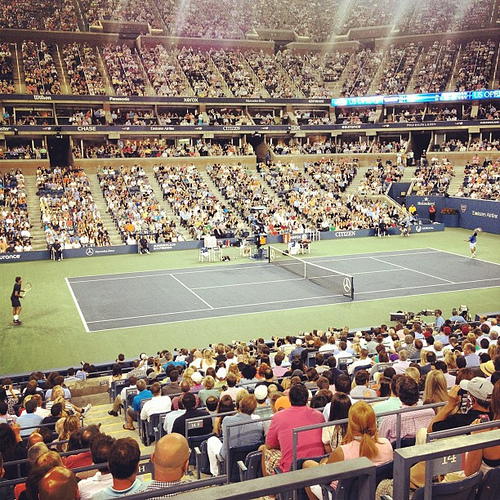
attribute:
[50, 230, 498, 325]
court — blue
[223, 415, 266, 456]
shirt — blue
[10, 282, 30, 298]
shirt — black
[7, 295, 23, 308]
shorts — black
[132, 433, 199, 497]
guy — bald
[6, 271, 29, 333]
tennis player — male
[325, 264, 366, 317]
symbol — Mercedes logo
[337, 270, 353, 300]
mercedes — logo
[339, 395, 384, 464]
hair — red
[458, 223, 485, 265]
player — serving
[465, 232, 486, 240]
shirt — blue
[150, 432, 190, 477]
head — bald 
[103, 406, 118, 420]
shoe — black 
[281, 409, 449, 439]
railing — gray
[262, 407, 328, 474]
shirt —  blue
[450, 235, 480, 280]
shorts — white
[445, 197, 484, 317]
shirt — blue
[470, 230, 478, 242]
shirt — blue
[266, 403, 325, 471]
shirt — pink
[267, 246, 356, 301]
net — tennis net